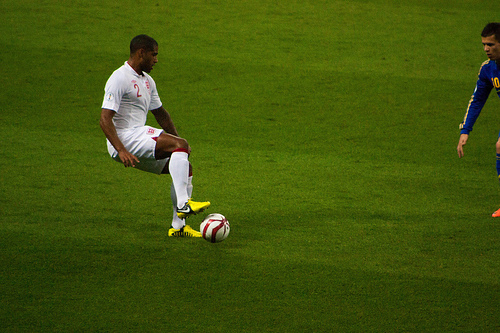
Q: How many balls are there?
A: One.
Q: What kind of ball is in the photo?
A: A soccer ball.